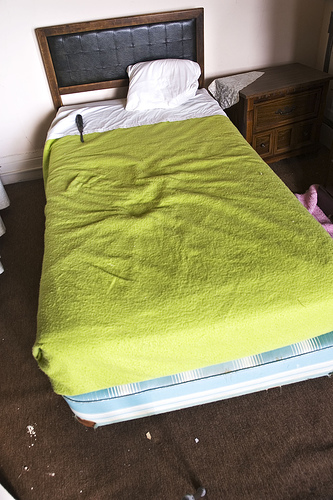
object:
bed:
[32, 98, 333, 430]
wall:
[2, 3, 325, 169]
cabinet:
[214, 61, 330, 163]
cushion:
[46, 16, 197, 89]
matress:
[60, 329, 333, 410]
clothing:
[293, 184, 333, 241]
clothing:
[207, 70, 267, 110]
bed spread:
[31, 87, 332, 395]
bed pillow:
[124, 58, 201, 113]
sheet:
[46, 85, 233, 137]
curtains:
[0, 173, 12, 275]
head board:
[33, 8, 207, 113]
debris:
[22, 419, 208, 494]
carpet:
[1, 147, 332, 497]